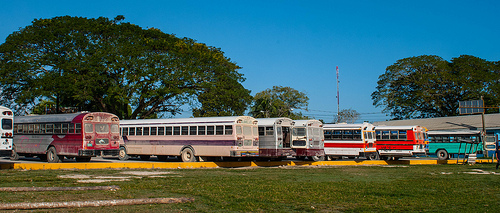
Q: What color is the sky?
A: Blue.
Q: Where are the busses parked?
A: On the pavement.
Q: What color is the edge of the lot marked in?
A: Yellow.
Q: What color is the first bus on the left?
A: White.